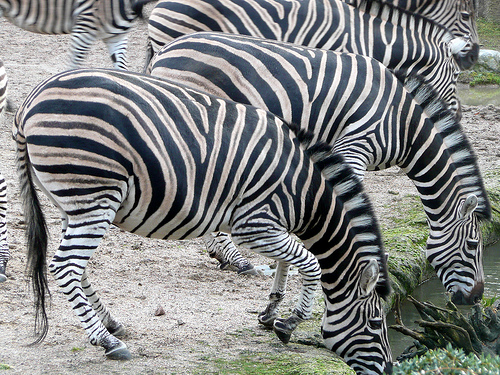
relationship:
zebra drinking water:
[0, 68, 406, 370] [369, 206, 499, 373]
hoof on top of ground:
[100, 340, 131, 361] [0, 247, 498, 374]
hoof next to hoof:
[100, 340, 131, 361] [274, 320, 295, 343]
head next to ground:
[313, 247, 400, 374] [0, 247, 498, 374]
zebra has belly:
[0, 68, 406, 370] [113, 174, 237, 241]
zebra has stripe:
[0, 68, 406, 370] [14, 103, 173, 236]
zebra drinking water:
[0, 68, 406, 370] [382, 203, 498, 359]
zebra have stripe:
[0, 68, 406, 370] [14, 103, 173, 236]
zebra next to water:
[0, 68, 406, 370] [369, 206, 499, 373]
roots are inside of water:
[399, 291, 499, 361] [369, 206, 499, 373]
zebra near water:
[0, 68, 406, 370] [369, 206, 499, 373]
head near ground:
[313, 247, 400, 374] [0, 247, 498, 374]